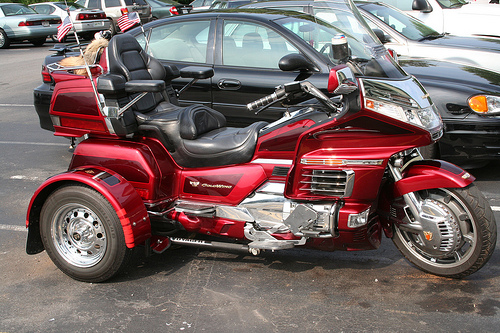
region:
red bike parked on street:
[18, 56, 432, 281]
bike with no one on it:
[35, 44, 443, 256]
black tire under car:
[381, 138, 479, 273]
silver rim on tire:
[33, 166, 131, 278]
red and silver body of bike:
[156, 143, 361, 245]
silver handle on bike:
[235, 76, 329, 140]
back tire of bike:
[40, 175, 132, 252]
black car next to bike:
[202, 11, 280, 98]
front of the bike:
[398, 93, 462, 144]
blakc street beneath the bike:
[158, 261, 243, 320]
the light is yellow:
[473, 95, 478, 105]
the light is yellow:
[472, 97, 481, 114]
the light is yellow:
[477, 102, 481, 109]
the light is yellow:
[469, 104, 480, 111]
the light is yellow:
[473, 96, 483, 108]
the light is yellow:
[471, 100, 481, 109]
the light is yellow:
[478, 96, 480, 116]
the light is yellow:
[476, 101, 489, 116]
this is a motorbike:
[40, 53, 377, 273]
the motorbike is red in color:
[299, 130, 372, 200]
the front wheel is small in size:
[402, 197, 488, 269]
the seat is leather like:
[175, 115, 248, 153]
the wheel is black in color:
[447, 195, 489, 248]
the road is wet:
[424, 286, 494, 321]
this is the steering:
[243, 72, 319, 122]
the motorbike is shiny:
[102, 150, 149, 182]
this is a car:
[222, 15, 261, 96]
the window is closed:
[235, 26, 272, 65]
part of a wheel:
[453, 190, 492, 277]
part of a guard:
[105, 183, 131, 211]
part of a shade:
[246, 257, 281, 285]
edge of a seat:
[205, 154, 236, 178]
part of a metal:
[167, 227, 227, 269]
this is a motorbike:
[39, 55, 442, 274]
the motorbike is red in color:
[103, 137, 142, 189]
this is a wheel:
[442, 193, 489, 281]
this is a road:
[203, 267, 391, 327]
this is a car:
[168, 17, 278, 72]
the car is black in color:
[423, 62, 455, 81]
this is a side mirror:
[274, 48, 315, 77]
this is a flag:
[53, 13, 82, 39]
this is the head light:
[468, 92, 495, 119]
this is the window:
[223, 25, 277, 50]